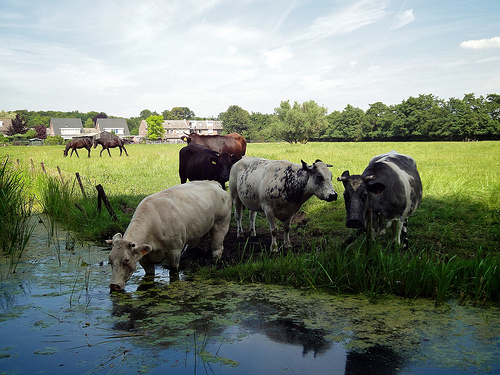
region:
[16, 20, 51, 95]
white clouds in blue sky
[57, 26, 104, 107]
white clouds in blue sky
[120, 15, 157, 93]
white clouds in blue sky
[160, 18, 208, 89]
white clouds in blue sky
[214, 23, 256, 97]
white clouds in blue sky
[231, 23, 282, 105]
white clouds in blue sky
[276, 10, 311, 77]
white clouds in blue sky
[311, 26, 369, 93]
white clouds in blue sky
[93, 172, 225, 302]
tan cow drinking water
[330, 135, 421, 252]
black and white cow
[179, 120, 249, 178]
brown cow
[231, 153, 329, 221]
white and black cow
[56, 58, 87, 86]
white clouds in blue sky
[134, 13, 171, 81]
white clouds in blue sky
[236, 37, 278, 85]
white clouds in blue sky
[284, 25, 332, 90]
white clouds in blue sky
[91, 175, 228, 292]
cow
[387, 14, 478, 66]
white clouds in blue sky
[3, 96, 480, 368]
cows in a farm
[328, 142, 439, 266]
a cow is white and black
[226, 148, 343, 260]
a white cow with black spots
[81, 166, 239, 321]
a cow is drinking water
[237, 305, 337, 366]
the reflection of a cow on the water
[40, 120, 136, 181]
two horses behind the cows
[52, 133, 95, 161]
a horse is eating grass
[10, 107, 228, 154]
homes in front of trees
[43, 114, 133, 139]
roof of homes are black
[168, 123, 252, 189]
a brown cow behind white cows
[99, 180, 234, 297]
cow drinking water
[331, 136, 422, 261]
white and black cow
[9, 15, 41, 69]
white clouds in blue sky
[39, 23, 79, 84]
white clouds in blue sky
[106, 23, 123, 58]
white clouds in blue sky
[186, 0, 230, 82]
white clouds in blue sky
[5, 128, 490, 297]
Animals in a field.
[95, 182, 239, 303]
White cow drinking water.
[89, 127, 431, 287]
Three cows standing behind a white cow.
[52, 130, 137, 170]
Two horses grazing in a field.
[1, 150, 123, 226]
A fence next to a body of water.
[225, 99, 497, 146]
Trees at the end of the pasture.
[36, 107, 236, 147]
Buildings located behind the two horses.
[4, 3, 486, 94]
A blue sky with white clouds.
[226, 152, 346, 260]
White cow with black spots looking to the right.